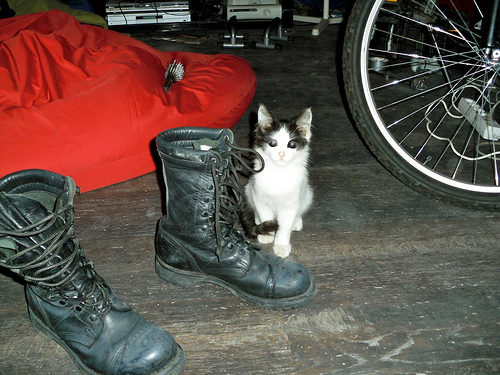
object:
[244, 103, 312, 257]
cat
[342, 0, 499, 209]
bicycle wheel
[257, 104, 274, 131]
right ear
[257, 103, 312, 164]
head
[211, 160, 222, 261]
laces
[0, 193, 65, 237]
laces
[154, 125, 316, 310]
boot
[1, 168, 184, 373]
boot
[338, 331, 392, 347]
scratches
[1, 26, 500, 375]
floor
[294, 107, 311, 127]
ears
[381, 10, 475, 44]
spokes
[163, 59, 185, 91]
hairbrush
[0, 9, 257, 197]
cushion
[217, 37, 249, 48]
push up bars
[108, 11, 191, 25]
stereo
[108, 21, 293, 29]
shelf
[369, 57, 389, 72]
duct tape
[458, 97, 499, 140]
surge protector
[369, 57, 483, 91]
stripe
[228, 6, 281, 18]
xbox 360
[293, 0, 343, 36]
base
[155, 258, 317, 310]
sole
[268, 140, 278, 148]
right eye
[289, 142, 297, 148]
left eye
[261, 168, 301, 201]
chest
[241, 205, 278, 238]
tail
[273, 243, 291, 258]
left paw